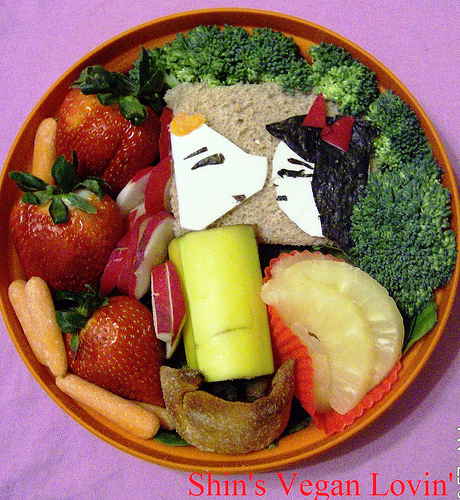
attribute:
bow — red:
[289, 103, 372, 150]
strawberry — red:
[59, 292, 167, 408]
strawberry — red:
[8, 166, 130, 286]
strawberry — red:
[56, 65, 161, 189]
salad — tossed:
[99, 106, 187, 357]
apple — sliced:
[128, 239, 185, 345]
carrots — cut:
[2, 272, 177, 442]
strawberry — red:
[61, 136, 139, 372]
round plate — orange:
[4, 3, 460, 484]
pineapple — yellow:
[168, 222, 279, 385]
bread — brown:
[169, 71, 345, 252]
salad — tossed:
[3, 24, 444, 450]